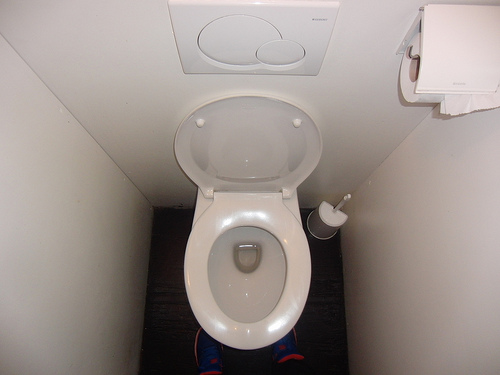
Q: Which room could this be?
A: It is a bathroom.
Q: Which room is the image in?
A: It is at the bathroom.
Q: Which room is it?
A: It is a bathroom.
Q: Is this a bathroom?
A: Yes, it is a bathroom.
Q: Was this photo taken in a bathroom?
A: Yes, it was taken in a bathroom.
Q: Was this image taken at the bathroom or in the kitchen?
A: It was taken at the bathroom.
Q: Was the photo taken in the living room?
A: No, the picture was taken in the bathroom.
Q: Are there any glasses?
A: No, there are no glasses.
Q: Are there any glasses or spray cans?
A: No, there are no glasses or spray cans.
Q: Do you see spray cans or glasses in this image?
A: No, there are no glasses or spray cans.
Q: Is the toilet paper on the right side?
A: Yes, the toilet paper is on the right of the image.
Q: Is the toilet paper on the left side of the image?
A: No, the toilet paper is on the right of the image.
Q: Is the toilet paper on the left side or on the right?
A: The toilet paper is on the right of the image.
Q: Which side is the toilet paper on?
A: The toilet paper is on the right of the image.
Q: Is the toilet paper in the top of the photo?
A: Yes, the toilet paper is in the top of the image.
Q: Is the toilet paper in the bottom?
A: No, the toilet paper is in the top of the image.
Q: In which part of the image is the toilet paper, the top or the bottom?
A: The toilet paper is in the top of the image.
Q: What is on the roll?
A: The toilet paper is on the roll.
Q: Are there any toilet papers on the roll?
A: Yes, there is a toilet paper on the roll.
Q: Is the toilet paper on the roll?
A: Yes, the toilet paper is on the roll.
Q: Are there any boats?
A: No, there are no boats.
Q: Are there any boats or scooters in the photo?
A: No, there are no boats or scooters.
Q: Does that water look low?
A: Yes, the water is low.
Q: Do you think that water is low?
A: Yes, the water is low.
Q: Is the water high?
A: No, the water is low.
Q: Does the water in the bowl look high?
A: No, the water is low.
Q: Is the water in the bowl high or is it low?
A: The water is low.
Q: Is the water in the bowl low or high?
A: The water is low.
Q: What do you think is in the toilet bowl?
A: The water is in the bowl.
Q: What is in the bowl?
A: The water is in the bowl.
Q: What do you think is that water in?
A: The water is in the bowl.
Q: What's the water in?
A: The water is in the bowl.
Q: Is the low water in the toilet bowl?
A: Yes, the water is in the bowl.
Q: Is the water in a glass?
A: No, the water is in the bowl.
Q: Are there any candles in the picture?
A: No, there are no candles.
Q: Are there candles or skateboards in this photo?
A: No, there are no candles or skateboards.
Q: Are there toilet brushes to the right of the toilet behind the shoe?
A: Yes, there is a toilet brush to the right of the toilet.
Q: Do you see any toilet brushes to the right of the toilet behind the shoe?
A: Yes, there is a toilet brush to the right of the toilet.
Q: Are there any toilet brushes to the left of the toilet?
A: No, the toilet brush is to the right of the toilet.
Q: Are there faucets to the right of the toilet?
A: No, there is a toilet brush to the right of the toilet.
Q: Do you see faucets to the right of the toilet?
A: No, there is a toilet brush to the right of the toilet.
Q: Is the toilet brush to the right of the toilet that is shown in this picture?
A: Yes, the toilet brush is to the right of the toilet.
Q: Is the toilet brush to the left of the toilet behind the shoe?
A: No, the toilet brush is to the right of the toilet.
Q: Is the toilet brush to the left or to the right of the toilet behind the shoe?
A: The toilet brush is to the right of the toilet.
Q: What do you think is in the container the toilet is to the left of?
A: The toilet brush is in the container.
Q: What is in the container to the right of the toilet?
A: The toilet brush is in the container.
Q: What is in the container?
A: The toilet brush is in the container.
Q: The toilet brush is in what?
A: The toilet brush is in the container.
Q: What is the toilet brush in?
A: The toilet brush is in the container.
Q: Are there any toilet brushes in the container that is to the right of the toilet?
A: Yes, there is a toilet brush in the container.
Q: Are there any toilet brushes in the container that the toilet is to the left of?
A: Yes, there is a toilet brush in the container.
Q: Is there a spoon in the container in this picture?
A: No, there is a toilet brush in the container.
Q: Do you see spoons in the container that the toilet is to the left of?
A: No, there is a toilet brush in the container.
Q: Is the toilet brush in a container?
A: Yes, the toilet brush is in a container.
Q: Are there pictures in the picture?
A: No, there are no pictures.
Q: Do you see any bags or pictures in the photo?
A: No, there are no pictures or bags.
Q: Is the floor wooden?
A: Yes, the floor is wooden.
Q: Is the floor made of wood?
A: Yes, the floor is made of wood.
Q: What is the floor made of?
A: The floor is made of wood.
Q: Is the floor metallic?
A: No, the floor is wooden.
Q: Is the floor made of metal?
A: No, the floor is made of wood.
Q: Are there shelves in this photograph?
A: No, there are no shelves.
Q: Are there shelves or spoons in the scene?
A: No, there are no shelves or spoons.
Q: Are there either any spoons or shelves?
A: No, there are no shelves or spoons.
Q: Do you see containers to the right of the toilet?
A: Yes, there is a container to the right of the toilet.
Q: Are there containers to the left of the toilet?
A: No, the container is to the right of the toilet.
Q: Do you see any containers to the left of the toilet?
A: No, the container is to the right of the toilet.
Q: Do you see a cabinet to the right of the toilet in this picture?
A: No, there is a container to the right of the toilet.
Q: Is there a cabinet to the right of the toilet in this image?
A: No, there is a container to the right of the toilet.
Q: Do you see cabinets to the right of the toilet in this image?
A: No, there is a container to the right of the toilet.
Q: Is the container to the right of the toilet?
A: Yes, the container is to the right of the toilet.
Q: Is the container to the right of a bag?
A: No, the container is to the right of the toilet.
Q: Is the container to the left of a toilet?
A: No, the container is to the right of a toilet.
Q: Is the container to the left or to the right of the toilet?
A: The container is to the right of the toilet.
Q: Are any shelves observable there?
A: No, there are no shelves.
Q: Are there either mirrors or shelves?
A: No, there are no shelves or mirrors.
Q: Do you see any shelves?
A: No, there are no shelves.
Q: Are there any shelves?
A: No, there are no shelves.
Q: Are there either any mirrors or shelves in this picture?
A: No, there are no shelves or mirrors.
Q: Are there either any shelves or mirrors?
A: No, there are no shelves or mirrors.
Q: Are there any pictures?
A: No, there are no pictures.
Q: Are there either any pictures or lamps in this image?
A: No, there are no pictures or lamps.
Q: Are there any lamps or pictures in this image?
A: No, there are no pictures or lamps.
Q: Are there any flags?
A: No, there are no flags.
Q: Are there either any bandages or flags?
A: No, there are no flags or bandages.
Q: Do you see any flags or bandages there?
A: No, there are no flags or bandages.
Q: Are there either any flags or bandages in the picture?
A: No, there are no flags or bandages.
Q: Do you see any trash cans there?
A: No, there are no trash cans.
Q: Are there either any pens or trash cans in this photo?
A: No, there are no trash cans or pens.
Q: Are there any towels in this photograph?
A: No, there are no towels.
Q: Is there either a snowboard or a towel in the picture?
A: No, there are no towels or snowboards.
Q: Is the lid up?
A: Yes, the lid is up.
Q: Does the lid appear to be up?
A: Yes, the lid is up.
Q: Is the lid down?
A: No, the lid is up.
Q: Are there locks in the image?
A: No, there are no locks.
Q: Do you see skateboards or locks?
A: No, there are no locks or skateboards.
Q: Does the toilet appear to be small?
A: Yes, the toilet is small.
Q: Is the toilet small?
A: Yes, the toilet is small.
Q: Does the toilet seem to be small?
A: Yes, the toilet is small.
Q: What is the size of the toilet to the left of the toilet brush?
A: The toilet is small.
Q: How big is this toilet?
A: The toilet is small.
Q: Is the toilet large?
A: No, the toilet is small.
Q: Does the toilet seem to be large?
A: No, the toilet is small.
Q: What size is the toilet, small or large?
A: The toilet is small.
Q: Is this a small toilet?
A: Yes, this is a small toilet.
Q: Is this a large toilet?
A: No, this is a small toilet.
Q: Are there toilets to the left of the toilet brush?
A: Yes, there is a toilet to the left of the toilet brush.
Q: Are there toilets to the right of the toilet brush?
A: No, the toilet is to the left of the toilet brush.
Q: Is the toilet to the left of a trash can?
A: No, the toilet is to the left of a toilet brush.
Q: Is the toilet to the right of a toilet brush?
A: No, the toilet is to the left of a toilet brush.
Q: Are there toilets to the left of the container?
A: Yes, there is a toilet to the left of the container.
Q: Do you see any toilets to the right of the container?
A: No, the toilet is to the left of the container.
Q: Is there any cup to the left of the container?
A: No, there is a toilet to the left of the container.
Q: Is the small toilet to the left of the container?
A: Yes, the toilet is to the left of the container.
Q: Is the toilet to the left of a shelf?
A: No, the toilet is to the left of the container.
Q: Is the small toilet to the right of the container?
A: No, the toilet is to the left of the container.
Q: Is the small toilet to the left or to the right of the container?
A: The toilet is to the left of the container.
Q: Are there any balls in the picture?
A: No, there are no balls.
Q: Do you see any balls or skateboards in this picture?
A: No, there are no balls or skateboards.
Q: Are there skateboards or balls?
A: No, there are no balls or skateboards.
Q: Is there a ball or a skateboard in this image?
A: No, there are no balls or skateboards.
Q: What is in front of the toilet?
A: The shoe is in front of the toilet.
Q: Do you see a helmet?
A: No, there are no helmets.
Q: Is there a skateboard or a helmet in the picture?
A: No, there are no helmets or skateboards.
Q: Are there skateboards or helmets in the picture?
A: No, there are no helmets or skateboards.